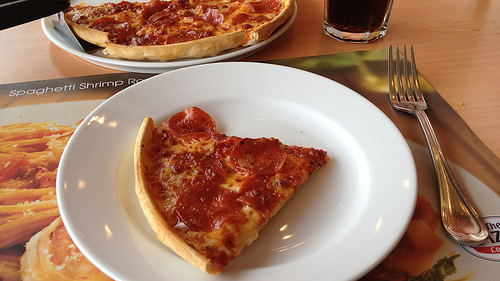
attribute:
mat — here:
[7, 78, 74, 276]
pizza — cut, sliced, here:
[125, 109, 339, 249]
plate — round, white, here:
[45, 55, 444, 279]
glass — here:
[312, 0, 414, 62]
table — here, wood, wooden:
[309, 5, 496, 203]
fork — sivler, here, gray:
[380, 37, 489, 261]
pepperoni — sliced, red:
[167, 101, 215, 140]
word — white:
[9, 82, 78, 97]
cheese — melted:
[145, 130, 211, 160]